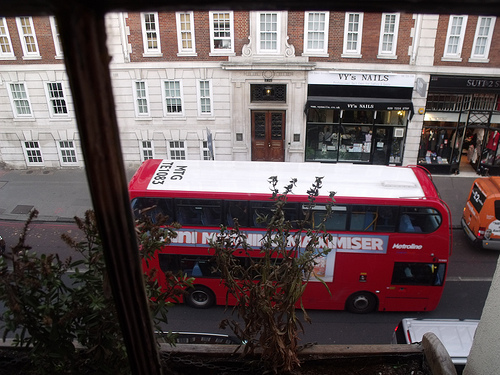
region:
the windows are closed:
[130, 15, 424, 56]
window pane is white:
[140, 16, 188, 63]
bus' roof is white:
[155, 163, 405, 219]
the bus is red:
[135, 202, 436, 319]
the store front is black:
[311, 87, 421, 164]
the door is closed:
[246, 103, 306, 161]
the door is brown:
[253, 115, 286, 157]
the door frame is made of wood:
[250, 107, 289, 162]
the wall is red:
[330, 28, 347, 56]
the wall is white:
[121, 118, 153, 168]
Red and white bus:
[110, 145, 466, 323]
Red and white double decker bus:
[99, 151, 470, 328]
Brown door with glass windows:
[227, 98, 299, 175]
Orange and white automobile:
[460, 167, 499, 262]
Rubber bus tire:
[334, 281, 391, 322]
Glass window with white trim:
[156, 72, 186, 128]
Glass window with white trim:
[124, 70, 156, 127]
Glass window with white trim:
[191, 67, 214, 126]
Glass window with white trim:
[299, 6, 340, 64]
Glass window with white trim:
[376, 3, 400, 62]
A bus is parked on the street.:
[122, 155, 459, 311]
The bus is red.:
[118, 155, 465, 319]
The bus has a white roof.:
[135, 146, 433, 203]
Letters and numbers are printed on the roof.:
[146, 153, 191, 189]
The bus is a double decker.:
[120, 150, 465, 320]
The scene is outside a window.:
[0, 6, 499, 373]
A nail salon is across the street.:
[292, 57, 432, 169]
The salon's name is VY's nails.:
[319, 68, 399, 84]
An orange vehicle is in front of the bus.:
[456, 165, 498, 252]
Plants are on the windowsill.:
[0, 157, 405, 374]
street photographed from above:
[5, 12, 498, 368]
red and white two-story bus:
[110, 150, 452, 320]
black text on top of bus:
[140, 150, 190, 190]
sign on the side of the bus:
[143, 225, 388, 280]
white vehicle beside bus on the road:
[310, 226, 480, 361]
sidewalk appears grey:
[5, 165, 85, 210]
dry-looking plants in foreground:
[0, 166, 335, 366]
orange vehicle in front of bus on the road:
[356, 167, 496, 292]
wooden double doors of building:
[232, 97, 299, 162]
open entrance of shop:
[439, 114, 499, 181]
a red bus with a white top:
[126, 158, 449, 313]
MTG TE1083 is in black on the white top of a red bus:
[150, 159, 187, 186]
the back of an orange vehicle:
[460, 175, 499, 247]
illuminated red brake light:
[473, 226, 487, 241]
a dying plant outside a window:
[202, 173, 347, 372]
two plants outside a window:
[5, 191, 192, 368]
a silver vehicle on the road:
[391, 313, 476, 368]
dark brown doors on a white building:
[247, 109, 288, 160]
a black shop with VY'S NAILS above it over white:
[308, 70, 413, 167]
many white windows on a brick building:
[126, 13, 493, 63]